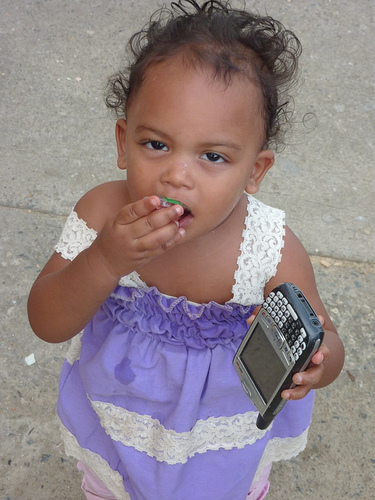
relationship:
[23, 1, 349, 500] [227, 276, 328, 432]
girl holding phone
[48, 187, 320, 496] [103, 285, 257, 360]
dress has ruffles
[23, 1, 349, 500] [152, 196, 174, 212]
girl eating ice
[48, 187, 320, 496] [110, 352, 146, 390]
dress has spot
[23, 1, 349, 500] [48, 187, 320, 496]
girl wearing dress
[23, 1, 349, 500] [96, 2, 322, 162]
girl has hair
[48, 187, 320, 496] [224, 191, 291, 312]
dress has lace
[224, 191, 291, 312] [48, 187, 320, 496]
lace sewn to dress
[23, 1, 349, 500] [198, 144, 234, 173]
girl has eye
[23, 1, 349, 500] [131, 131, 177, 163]
girl has eye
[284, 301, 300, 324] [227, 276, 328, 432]
button on phone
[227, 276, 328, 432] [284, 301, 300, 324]
phone has button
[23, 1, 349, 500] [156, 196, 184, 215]
girl eating candy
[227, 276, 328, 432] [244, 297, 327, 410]
phone in hand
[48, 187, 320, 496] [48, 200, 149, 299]
dress has strap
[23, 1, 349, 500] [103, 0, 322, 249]
girl has head